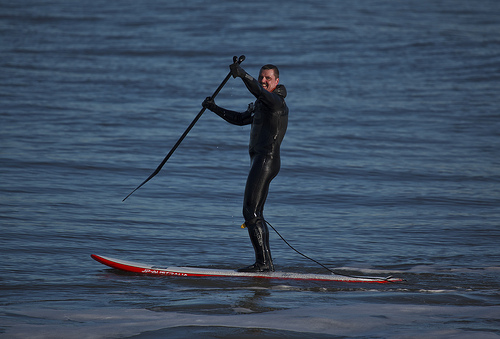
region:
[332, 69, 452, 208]
Water is blue color.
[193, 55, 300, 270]
one man is standing in board.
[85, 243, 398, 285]
Board is red and white color.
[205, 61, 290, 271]
Man is wearing black dress.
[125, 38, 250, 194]
Man is holding oars in hand.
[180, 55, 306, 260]
Man is wet.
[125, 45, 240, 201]
Oars is black color.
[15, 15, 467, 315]
Day time picture.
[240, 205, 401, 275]
Man is holding the wire between the legs.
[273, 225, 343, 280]
Wire is black color.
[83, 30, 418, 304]
Man is on surfboard.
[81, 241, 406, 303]
Surfboard is red and white.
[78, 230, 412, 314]
Surfboard is in water.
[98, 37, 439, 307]
Man is wearing leg leash.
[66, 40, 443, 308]
Man is holding pole.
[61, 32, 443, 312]
The pole is pointed.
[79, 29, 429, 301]
The pole is black.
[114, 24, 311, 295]
Man wearing a wetsuit.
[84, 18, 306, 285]
The wetsuit is black.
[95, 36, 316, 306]
The wetsuit is wet.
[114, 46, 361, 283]
man on paddleboard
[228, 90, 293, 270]
black wetsuit on man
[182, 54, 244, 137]
two hands on handle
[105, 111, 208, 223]
black paddle above water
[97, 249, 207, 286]
red edge on white board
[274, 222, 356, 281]
black cord attached to board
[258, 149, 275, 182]
light reflection on wetsuit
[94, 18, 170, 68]
ripples on water surface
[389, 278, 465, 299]
ripple made by paddle board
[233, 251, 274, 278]
black booties on man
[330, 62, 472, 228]
The water is blue.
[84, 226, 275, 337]
The board is white and red.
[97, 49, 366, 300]
He is standing on the board.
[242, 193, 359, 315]
The rope is connected to the board.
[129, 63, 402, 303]
He is wearing a wet suit.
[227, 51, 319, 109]
His hair is brown.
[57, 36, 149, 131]
The water is calm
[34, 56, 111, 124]
The water is blue.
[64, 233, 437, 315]
The edge of the board is red.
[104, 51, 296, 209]
He has a pole in his hand.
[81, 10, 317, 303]
A man standing on a surf board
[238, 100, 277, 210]
The man is wearing a black wet suit.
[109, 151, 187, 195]
A black paddle.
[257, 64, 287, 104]
A man smiling at the camera.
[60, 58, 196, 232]
A body of blue water.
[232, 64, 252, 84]
A gloved hand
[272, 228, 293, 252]
A cord that runs from the wet suit to the surf board.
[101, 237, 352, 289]
the surf board is white and red.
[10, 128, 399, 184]
A small wave in the water.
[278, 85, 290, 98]
A black hood.